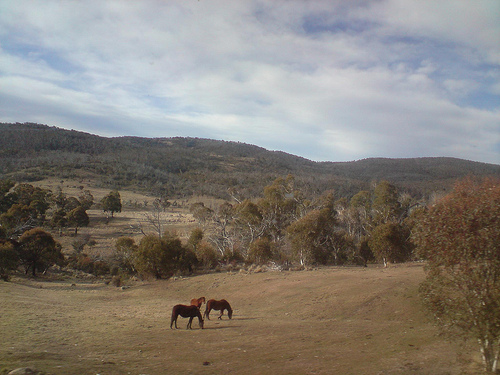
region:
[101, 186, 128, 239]
green tree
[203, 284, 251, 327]
grazing brown horse facing right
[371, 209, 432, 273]
green tree on right side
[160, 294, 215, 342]
front grazing brown horse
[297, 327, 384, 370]
brown dying grass on ground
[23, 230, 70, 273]
left green tree on left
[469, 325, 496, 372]
tree trunk on right side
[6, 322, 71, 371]
dying grass on lower left side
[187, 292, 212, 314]
middle horse facing camera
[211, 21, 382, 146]
cloudy blue sky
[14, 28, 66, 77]
Sky is blue color.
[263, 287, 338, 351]
Ground is brown color.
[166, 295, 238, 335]
Three horse are standing in the ground.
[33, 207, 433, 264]
Trees are behind the horse.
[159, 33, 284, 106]
Clouds are white color.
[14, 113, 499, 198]
Mountains are behind the trees.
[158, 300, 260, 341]
Shadow falls on the ground.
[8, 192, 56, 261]
Trees are green color.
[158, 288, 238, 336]
Horse are brown color.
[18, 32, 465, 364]
Day time picture.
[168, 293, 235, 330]
these are three horses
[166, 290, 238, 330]
the horses are feeding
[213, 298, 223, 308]
the horse is brown in color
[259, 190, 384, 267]
these are the trees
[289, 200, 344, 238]
the leaves are brown in color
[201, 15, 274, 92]
the clouds are in the sky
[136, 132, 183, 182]
this is a hill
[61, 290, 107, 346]
the place is full of soil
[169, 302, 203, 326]
the horse is big in size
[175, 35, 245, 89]
the clouds are white in color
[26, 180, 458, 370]
Horses in a large field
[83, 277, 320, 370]
The horses are grazing in a pasture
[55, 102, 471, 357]
Animals in a wide open field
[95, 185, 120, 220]
The tree is in a forest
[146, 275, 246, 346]
The horses are looking for fresh grass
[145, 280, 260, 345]
Three horses are grazing together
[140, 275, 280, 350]
Two stallions and one mare in the field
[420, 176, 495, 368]
The tree is on a hillside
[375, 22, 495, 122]
This sky is mostly cloudy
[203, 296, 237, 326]
The horse has its head down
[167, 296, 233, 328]
three wild horses grazing in the grass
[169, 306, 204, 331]
dark colored horse eating grass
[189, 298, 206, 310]
light brown horse looking at other two horses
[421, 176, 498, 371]
tall tree in the foreground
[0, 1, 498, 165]
high altitude clouds in the sky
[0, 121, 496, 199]
hills in the background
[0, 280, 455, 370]
open grassy field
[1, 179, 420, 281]
various trees in the background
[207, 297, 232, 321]
horse is grazing in an open field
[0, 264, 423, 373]
meadow where horses are grazing